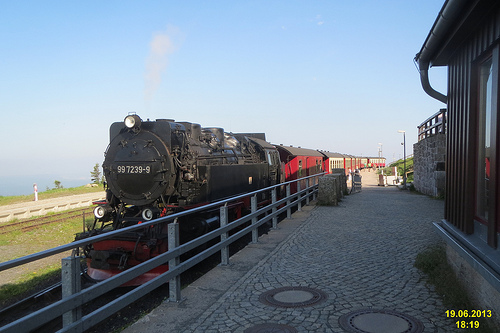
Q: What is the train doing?
A: Pulling in.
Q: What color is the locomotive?
A: Black.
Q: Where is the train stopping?
A: Station.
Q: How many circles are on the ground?
A: Two.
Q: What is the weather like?
A: Sunny.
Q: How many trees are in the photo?
A: Two.